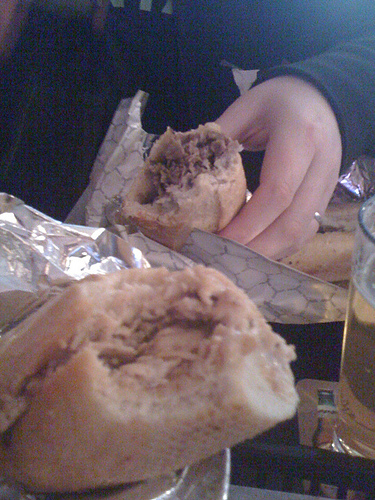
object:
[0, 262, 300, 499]
sandwich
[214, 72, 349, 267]
hand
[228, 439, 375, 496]
basket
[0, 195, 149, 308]
foil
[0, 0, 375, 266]
person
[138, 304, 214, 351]
meat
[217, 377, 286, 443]
breadh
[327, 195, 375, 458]
cup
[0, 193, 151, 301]
wrapper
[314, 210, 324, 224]
ring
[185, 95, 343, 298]
finger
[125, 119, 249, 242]
humberger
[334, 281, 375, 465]
juice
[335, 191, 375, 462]
glass